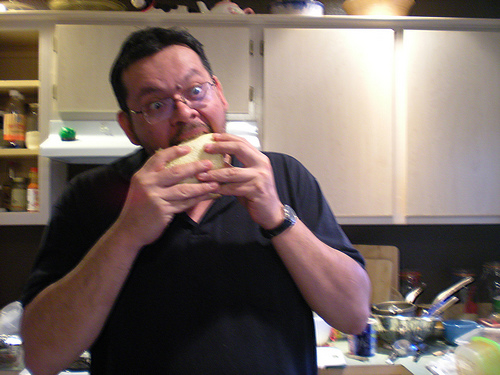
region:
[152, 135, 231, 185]
A sandwhich.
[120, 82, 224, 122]
A pair of glasses.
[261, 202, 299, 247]
A black wristwatch.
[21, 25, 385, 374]
A man eating a sandwichl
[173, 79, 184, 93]
A mole on a mans face.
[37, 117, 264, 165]
A white over the stove exhaust fan.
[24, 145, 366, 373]
A black collar t-shirt.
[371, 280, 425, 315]
A silver pot.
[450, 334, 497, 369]
A plastic container with a green lid.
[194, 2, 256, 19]
A white and pink teapot.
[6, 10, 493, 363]
A man eating in the kitchen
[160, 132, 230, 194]
A sandwich with white bread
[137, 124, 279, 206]
A small sandwich in the man's hands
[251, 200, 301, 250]
A black watch on the man's wrist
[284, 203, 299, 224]
The shiny silver watch face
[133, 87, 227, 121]
Glasses on the man's face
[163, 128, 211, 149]
The man's mouth is open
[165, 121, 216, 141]
The man has a mustache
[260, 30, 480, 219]
Two white cabinets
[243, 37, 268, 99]
Small screws on the cabinets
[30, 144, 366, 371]
The man is wearing a shirt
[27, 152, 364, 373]
The shirt is black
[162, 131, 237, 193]
The bread is light colored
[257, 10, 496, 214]
The cabinets are white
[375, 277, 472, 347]
The pans are silver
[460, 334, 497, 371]
An empty plastic container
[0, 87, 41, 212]
Bottles are on the shelves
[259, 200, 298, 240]
The man has a watch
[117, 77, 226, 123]
The man has glasses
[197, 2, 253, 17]
A tea pot is on top of the cupboard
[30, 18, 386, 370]
guy with short hair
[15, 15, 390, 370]
guy with thin glasses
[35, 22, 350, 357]
guys with black shirt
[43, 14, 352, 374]
guy with black hair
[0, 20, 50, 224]
opened cabinet with seasonings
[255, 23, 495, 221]
white wooden cabinets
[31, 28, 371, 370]
guy taking big bite out of food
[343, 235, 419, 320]
two wooden cutting boards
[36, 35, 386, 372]
guy wearing watch on left wrist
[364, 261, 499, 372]
dishes on the counter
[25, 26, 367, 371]
A man is eating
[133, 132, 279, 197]
The man is holding a sandwich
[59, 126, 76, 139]
A green ball is sitting on an overhang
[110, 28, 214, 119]
The man has dark hair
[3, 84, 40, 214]
Bottles are in the cupboard